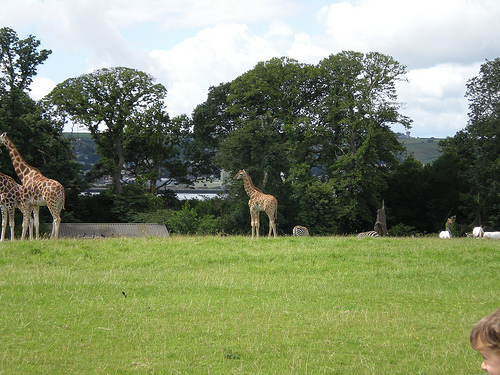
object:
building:
[71, 157, 338, 201]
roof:
[77, 157, 229, 192]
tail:
[274, 198, 279, 224]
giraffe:
[233, 168, 279, 239]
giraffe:
[1, 171, 35, 241]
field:
[41, 107, 492, 168]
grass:
[0, 235, 499, 374]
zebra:
[357, 230, 381, 239]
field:
[1, 232, 498, 369]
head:
[469, 310, 500, 375]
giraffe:
[0, 132, 65, 241]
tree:
[473, 110, 500, 237]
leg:
[17, 206, 29, 242]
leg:
[31, 204, 41, 240]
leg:
[254, 212, 260, 238]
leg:
[250, 210, 256, 237]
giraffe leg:
[266, 211, 277, 237]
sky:
[0, 0, 500, 138]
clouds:
[404, 20, 474, 64]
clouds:
[151, 26, 270, 72]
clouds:
[289, 27, 327, 62]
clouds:
[29, 77, 51, 99]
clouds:
[435, 105, 464, 135]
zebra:
[291, 226, 309, 239]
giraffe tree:
[230, 165, 295, 235]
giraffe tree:
[1, 126, 81, 247]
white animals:
[438, 230, 454, 239]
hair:
[469, 310, 500, 358]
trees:
[240, 56, 304, 98]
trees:
[314, 51, 411, 109]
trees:
[66, 66, 159, 119]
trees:
[206, 86, 226, 129]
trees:
[391, 136, 448, 238]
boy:
[468, 310, 499, 373]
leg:
[48, 203, 61, 239]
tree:
[469, 66, 499, 116]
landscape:
[0, 0, 500, 375]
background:
[2, 122, 97, 203]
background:
[150, 150, 294, 205]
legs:
[0, 203, 8, 243]